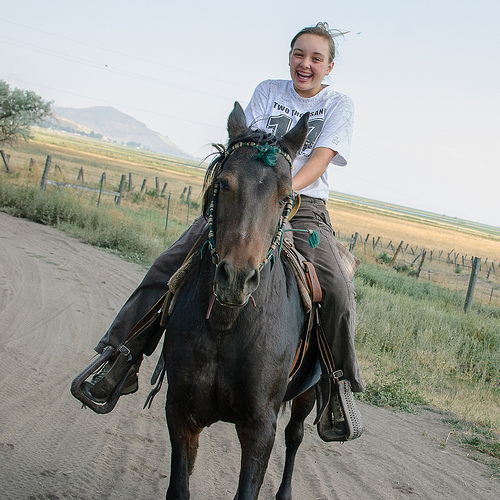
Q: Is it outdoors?
A: Yes, it is outdoors.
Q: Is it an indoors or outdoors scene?
A: It is outdoors.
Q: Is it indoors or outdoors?
A: It is outdoors.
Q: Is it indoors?
A: No, it is outdoors.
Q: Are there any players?
A: No, there are no players.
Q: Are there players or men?
A: No, there are no players or men.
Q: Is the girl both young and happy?
A: Yes, the girl is young and happy.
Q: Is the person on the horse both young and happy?
A: Yes, the girl is young and happy.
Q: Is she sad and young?
A: No, the girl is young but happy.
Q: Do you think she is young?
A: Yes, the girl is young.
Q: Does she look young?
A: Yes, the girl is young.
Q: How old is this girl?
A: The girl is young.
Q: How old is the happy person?
A: The girl is young.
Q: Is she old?
A: No, the girl is young.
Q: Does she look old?
A: No, the girl is young.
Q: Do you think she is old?
A: No, the girl is young.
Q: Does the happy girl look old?
A: No, the girl is young.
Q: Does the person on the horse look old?
A: No, the girl is young.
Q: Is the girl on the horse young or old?
A: The girl is young.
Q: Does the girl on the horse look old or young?
A: The girl is young.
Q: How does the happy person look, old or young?
A: The girl is young.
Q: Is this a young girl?
A: Yes, this is a young girl.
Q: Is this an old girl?
A: No, this is a young girl.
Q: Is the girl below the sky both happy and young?
A: Yes, the girl is happy and young.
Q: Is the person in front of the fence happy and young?
A: Yes, the girl is happy and young.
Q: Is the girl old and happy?
A: No, the girl is happy but young.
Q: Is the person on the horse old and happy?
A: No, the girl is happy but young.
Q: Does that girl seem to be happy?
A: Yes, the girl is happy.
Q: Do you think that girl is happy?
A: Yes, the girl is happy.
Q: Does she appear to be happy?
A: Yes, the girl is happy.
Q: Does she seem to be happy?
A: Yes, the girl is happy.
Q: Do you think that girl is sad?
A: No, the girl is happy.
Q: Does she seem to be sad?
A: No, the girl is happy.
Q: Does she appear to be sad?
A: No, the girl is happy.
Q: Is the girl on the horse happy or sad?
A: The girl is happy.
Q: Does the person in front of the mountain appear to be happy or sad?
A: The girl is happy.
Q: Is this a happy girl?
A: Yes, this is a happy girl.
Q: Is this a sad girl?
A: No, this is a happy girl.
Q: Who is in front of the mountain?
A: The girl is in front of the mountain.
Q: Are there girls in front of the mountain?
A: Yes, there is a girl in front of the mountain.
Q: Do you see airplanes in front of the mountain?
A: No, there is a girl in front of the mountain.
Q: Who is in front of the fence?
A: The girl is in front of the fence.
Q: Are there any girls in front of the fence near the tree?
A: Yes, there is a girl in front of the fence.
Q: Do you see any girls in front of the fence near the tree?
A: Yes, there is a girl in front of the fence.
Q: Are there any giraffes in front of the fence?
A: No, there is a girl in front of the fence.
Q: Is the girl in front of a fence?
A: Yes, the girl is in front of a fence.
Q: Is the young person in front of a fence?
A: Yes, the girl is in front of a fence.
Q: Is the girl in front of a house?
A: No, the girl is in front of a fence.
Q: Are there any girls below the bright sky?
A: Yes, there is a girl below the sky.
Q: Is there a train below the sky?
A: No, there is a girl below the sky.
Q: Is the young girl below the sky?
A: Yes, the girl is below the sky.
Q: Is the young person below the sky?
A: Yes, the girl is below the sky.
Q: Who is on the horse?
A: The girl is on the horse.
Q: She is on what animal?
A: The girl is on the horse.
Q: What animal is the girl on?
A: The girl is on the horse.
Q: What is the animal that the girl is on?
A: The animal is a horse.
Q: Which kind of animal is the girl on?
A: The girl is on the horse.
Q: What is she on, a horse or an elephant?
A: The girl is on a horse.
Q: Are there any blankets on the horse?
A: No, there is a girl on the horse.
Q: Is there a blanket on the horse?
A: No, there is a girl on the horse.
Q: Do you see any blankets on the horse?
A: No, there is a girl on the horse.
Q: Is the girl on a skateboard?
A: No, the girl is on the horse.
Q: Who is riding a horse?
A: The girl is riding a horse.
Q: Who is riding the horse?
A: The girl is riding a horse.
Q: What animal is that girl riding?
A: The girl is riding a horse.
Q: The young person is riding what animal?
A: The girl is riding a horse.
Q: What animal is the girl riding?
A: The girl is riding a horse.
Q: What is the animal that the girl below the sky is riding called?
A: The animal is a horse.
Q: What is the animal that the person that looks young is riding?
A: The animal is a horse.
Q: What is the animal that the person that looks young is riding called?
A: The animal is a horse.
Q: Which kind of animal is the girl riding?
A: The girl is riding a horse.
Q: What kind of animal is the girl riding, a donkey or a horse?
A: The girl is riding a horse.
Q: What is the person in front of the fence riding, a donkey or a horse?
A: The girl is riding a horse.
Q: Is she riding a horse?
A: Yes, the girl is riding a horse.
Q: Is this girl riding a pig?
A: No, the girl is riding a horse.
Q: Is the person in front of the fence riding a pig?
A: No, the girl is riding a horse.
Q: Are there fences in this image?
A: Yes, there is a fence.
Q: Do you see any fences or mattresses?
A: Yes, there is a fence.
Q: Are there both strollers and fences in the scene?
A: No, there is a fence but no strollers.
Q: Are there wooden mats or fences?
A: Yes, there is a wood fence.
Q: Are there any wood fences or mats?
A: Yes, there is a wood fence.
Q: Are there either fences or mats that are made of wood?
A: Yes, the fence is made of wood.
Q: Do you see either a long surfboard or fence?
A: Yes, there is a long fence.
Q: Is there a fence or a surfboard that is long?
A: Yes, the fence is long.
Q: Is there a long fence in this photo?
A: Yes, there is a long fence.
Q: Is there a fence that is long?
A: Yes, there is a fence that is long.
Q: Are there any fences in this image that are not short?
A: Yes, there is a long fence.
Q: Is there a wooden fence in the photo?
A: Yes, there is a wood fence.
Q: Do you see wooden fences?
A: Yes, there is a wood fence.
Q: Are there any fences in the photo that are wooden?
A: Yes, there is a fence that is wooden.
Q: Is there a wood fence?
A: Yes, there is a fence that is made of wood.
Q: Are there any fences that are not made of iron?
A: Yes, there is a fence that is made of wood.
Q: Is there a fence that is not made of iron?
A: Yes, there is a fence that is made of wood.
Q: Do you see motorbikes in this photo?
A: No, there are no motorbikes.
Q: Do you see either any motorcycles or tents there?
A: No, there are no motorcycles or tents.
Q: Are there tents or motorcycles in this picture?
A: No, there are no motorcycles or tents.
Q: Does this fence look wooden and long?
A: Yes, the fence is wooden and long.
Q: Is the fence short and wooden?
A: No, the fence is wooden but long.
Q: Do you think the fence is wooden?
A: Yes, the fence is wooden.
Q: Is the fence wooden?
A: Yes, the fence is wooden.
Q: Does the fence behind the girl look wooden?
A: Yes, the fence is wooden.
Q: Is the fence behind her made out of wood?
A: Yes, the fence is made of wood.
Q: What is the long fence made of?
A: The fence is made of wood.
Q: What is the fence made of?
A: The fence is made of wood.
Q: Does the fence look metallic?
A: No, the fence is wooden.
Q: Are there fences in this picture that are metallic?
A: No, there is a fence but it is wooden.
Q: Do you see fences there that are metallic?
A: No, there is a fence but it is wooden.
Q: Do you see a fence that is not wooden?
A: No, there is a fence but it is wooden.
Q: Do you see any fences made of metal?
A: No, there is a fence but it is made of wood.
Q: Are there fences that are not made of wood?
A: No, there is a fence but it is made of wood.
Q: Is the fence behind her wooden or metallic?
A: The fence is wooden.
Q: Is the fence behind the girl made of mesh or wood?
A: The fence is made of wood.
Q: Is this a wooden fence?
A: Yes, this is a wooden fence.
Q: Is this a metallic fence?
A: No, this is a wooden fence.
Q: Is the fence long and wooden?
A: Yes, the fence is long and wooden.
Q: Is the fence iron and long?
A: No, the fence is long but wooden.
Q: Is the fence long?
A: Yes, the fence is long.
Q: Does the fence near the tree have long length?
A: Yes, the fence is long.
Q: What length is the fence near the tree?
A: The fence is long.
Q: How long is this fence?
A: The fence is long.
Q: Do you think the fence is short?
A: No, the fence is long.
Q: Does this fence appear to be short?
A: No, the fence is long.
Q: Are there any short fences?
A: No, there is a fence but it is long.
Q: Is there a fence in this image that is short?
A: No, there is a fence but it is long.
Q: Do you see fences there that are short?
A: No, there is a fence but it is long.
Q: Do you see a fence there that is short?
A: No, there is a fence but it is long.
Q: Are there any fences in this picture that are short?
A: No, there is a fence but it is long.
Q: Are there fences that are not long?
A: No, there is a fence but it is long.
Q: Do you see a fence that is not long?
A: No, there is a fence but it is long.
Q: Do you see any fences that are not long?
A: No, there is a fence but it is long.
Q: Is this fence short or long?
A: The fence is long.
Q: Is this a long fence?
A: Yes, this is a long fence.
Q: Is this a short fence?
A: No, this is a long fence.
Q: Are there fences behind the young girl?
A: Yes, there is a fence behind the girl.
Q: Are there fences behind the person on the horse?
A: Yes, there is a fence behind the girl.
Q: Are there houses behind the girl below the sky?
A: No, there is a fence behind the girl.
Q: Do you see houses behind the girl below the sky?
A: No, there is a fence behind the girl.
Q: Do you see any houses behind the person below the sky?
A: No, there is a fence behind the girl.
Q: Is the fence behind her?
A: Yes, the fence is behind the girl.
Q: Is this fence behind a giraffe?
A: No, the fence is behind the girl.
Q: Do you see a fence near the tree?
A: Yes, there is a fence near the tree.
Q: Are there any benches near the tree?
A: No, there is a fence near the tree.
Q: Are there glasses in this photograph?
A: No, there are no glasses.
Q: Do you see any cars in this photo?
A: No, there are no cars.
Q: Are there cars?
A: No, there are no cars.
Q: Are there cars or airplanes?
A: No, there are no cars or airplanes.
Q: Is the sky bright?
A: Yes, the sky is bright.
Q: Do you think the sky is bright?
A: Yes, the sky is bright.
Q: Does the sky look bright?
A: Yes, the sky is bright.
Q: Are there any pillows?
A: No, there are no pillows.